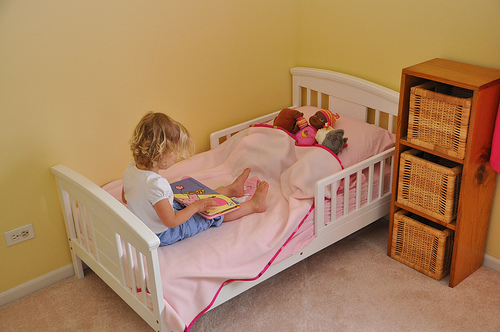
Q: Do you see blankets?
A: Yes, there is a blanket.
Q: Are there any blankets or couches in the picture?
A: Yes, there is a blanket.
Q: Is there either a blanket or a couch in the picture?
A: Yes, there is a blanket.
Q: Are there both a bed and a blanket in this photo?
A: Yes, there are both a blanket and a bed.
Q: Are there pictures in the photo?
A: No, there are no pictures.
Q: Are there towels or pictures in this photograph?
A: No, there are no pictures or towels.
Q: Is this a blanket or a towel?
A: This is a blanket.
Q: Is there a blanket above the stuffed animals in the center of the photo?
A: Yes, there is a blanket above the stuffed animals.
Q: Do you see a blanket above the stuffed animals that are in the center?
A: Yes, there is a blanket above the stuffed animals.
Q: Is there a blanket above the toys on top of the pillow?
A: Yes, there is a blanket above the stuffed animals.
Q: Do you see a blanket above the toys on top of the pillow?
A: Yes, there is a blanket above the stuffed animals.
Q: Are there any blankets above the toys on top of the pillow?
A: Yes, there is a blanket above the stuffed animals.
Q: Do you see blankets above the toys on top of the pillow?
A: Yes, there is a blanket above the stuffed animals.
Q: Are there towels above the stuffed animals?
A: No, there is a blanket above the stuffed animals.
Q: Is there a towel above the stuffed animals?
A: No, there is a blanket above the stuffed animals.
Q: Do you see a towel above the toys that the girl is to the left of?
A: No, there is a blanket above the stuffed animals.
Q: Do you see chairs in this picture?
A: No, there are no chairs.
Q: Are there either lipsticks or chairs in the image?
A: No, there are no chairs or lipsticks.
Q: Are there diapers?
A: No, there are no diapers.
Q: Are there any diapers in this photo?
A: No, there are no diapers.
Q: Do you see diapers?
A: No, there are no diapers.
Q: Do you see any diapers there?
A: No, there are no diapers.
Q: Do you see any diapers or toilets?
A: No, there are no diapers or toilets.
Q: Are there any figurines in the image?
A: No, there are no figurines.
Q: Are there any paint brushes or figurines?
A: No, there are no figurines or paint brushes.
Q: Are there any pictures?
A: No, there are no pictures.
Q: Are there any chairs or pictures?
A: No, there are no pictures or chairs.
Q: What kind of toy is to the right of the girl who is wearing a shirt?
A: The toys are stuffed animals.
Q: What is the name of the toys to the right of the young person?
A: The toys are stuffed animals.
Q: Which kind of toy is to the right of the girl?
A: The toys are stuffed animals.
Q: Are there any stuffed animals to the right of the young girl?
A: Yes, there are stuffed animals to the right of the girl.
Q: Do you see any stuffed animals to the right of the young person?
A: Yes, there are stuffed animals to the right of the girl.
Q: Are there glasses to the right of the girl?
A: No, there are stuffed animals to the right of the girl.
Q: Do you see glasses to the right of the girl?
A: No, there are stuffed animals to the right of the girl.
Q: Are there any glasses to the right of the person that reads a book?
A: No, there are stuffed animals to the right of the girl.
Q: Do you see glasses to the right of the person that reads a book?
A: No, there are stuffed animals to the right of the girl.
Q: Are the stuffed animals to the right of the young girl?
A: Yes, the stuffed animals are to the right of the girl.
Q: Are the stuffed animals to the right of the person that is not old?
A: Yes, the stuffed animals are to the right of the girl.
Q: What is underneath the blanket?
A: The stuffed animals are underneath the blanket.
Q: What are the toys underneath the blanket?
A: The toys are stuffed animals.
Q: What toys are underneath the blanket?
A: The toys are stuffed animals.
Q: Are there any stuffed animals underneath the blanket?
A: Yes, there are stuffed animals underneath the blanket.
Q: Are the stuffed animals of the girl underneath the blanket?
A: Yes, the stuffed animals are underneath the blanket.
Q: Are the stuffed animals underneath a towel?
A: No, the stuffed animals are underneath the blanket.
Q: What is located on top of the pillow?
A: The stuffed animals are on top of the pillow.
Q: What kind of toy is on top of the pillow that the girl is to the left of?
A: The toys are stuffed animals.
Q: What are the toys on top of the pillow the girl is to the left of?
A: The toys are stuffed animals.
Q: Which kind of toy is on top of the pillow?
A: The toys are stuffed animals.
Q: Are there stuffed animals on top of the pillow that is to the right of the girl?
A: Yes, there are stuffed animals on top of the pillow.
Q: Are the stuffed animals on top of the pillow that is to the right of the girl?
A: Yes, the stuffed animals are on top of the pillow.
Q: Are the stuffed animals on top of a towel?
A: No, the stuffed animals are on top of the pillow.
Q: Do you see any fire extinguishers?
A: No, there are no fire extinguishers.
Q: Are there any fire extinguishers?
A: No, there are no fire extinguishers.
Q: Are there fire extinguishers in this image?
A: No, there are no fire extinguishers.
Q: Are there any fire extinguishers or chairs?
A: No, there are no fire extinguishers or chairs.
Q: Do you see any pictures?
A: No, there are no pictures.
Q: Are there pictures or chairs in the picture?
A: No, there are no pictures or chairs.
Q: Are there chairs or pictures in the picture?
A: No, there are no pictures or chairs.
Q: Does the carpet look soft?
A: Yes, the carpet is soft.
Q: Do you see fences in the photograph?
A: No, there are no fences.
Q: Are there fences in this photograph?
A: No, there are no fences.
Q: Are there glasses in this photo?
A: No, there are no glasses.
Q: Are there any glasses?
A: No, there are no glasses.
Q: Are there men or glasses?
A: No, there are no glasses or men.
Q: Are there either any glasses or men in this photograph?
A: No, there are no glasses or men.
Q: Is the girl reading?
A: Yes, the girl is reading.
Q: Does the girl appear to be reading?
A: Yes, the girl is reading.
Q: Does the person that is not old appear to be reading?
A: Yes, the girl is reading.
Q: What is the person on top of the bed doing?
A: The girl is reading.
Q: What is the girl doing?
A: The girl is reading.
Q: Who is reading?
A: The girl is reading.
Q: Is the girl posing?
A: No, the girl is reading.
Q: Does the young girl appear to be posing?
A: No, the girl is reading.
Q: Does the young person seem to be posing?
A: No, the girl is reading.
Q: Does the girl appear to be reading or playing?
A: The girl is reading.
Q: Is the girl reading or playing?
A: The girl is reading.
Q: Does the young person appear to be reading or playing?
A: The girl is reading.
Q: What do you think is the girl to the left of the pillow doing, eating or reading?
A: The girl is reading.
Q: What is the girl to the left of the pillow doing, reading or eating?
A: The girl is reading.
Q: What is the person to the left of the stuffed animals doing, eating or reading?
A: The girl is reading.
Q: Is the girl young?
A: Yes, the girl is young.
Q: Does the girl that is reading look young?
A: Yes, the girl is young.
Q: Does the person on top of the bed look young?
A: Yes, the girl is young.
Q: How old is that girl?
A: The girl is young.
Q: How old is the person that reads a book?
A: The girl is young.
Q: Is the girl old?
A: No, the girl is young.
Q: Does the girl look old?
A: No, the girl is young.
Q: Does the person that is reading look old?
A: No, the girl is young.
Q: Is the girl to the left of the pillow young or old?
A: The girl is young.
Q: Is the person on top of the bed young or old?
A: The girl is young.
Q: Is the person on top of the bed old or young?
A: The girl is young.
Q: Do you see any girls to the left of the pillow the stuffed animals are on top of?
A: Yes, there is a girl to the left of the pillow.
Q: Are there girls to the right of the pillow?
A: No, the girl is to the left of the pillow.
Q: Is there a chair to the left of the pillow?
A: No, there is a girl to the left of the pillow.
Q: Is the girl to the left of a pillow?
A: Yes, the girl is to the left of a pillow.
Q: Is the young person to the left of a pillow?
A: Yes, the girl is to the left of a pillow.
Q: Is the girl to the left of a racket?
A: No, the girl is to the left of a pillow.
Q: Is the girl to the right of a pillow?
A: No, the girl is to the left of a pillow.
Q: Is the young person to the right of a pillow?
A: No, the girl is to the left of a pillow.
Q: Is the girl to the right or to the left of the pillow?
A: The girl is to the left of the pillow.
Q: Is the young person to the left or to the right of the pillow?
A: The girl is to the left of the pillow.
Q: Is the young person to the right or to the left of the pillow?
A: The girl is to the left of the pillow.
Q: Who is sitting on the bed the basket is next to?
A: The girl is sitting on the bed.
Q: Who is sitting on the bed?
A: The girl is sitting on the bed.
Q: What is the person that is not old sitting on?
A: The girl is sitting on the bed.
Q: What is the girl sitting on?
A: The girl is sitting on the bed.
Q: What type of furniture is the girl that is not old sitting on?
A: The girl is sitting on the bed.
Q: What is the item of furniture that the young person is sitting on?
A: The piece of furniture is a bed.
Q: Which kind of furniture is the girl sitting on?
A: The girl is sitting on the bed.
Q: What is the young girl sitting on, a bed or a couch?
A: The girl is sitting on a bed.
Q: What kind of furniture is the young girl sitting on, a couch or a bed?
A: The girl is sitting on a bed.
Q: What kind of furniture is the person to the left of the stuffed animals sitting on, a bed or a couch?
A: The girl is sitting on a bed.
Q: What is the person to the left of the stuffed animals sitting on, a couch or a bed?
A: The girl is sitting on a bed.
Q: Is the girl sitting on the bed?
A: Yes, the girl is sitting on the bed.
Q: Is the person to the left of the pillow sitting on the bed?
A: Yes, the girl is sitting on the bed.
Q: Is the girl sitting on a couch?
A: No, the girl is sitting on the bed.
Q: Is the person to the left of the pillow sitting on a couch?
A: No, the girl is sitting on the bed.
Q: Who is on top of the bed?
A: The girl is on top of the bed.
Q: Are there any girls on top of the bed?
A: Yes, there is a girl on top of the bed.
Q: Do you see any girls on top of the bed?
A: Yes, there is a girl on top of the bed.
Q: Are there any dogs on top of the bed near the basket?
A: No, there is a girl on top of the bed.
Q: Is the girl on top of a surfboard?
A: No, the girl is on top of the bed.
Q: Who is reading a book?
A: The girl is reading a book.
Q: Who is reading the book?
A: The girl is reading a book.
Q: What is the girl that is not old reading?
A: The girl is reading a book.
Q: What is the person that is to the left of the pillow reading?
A: The girl is reading a book.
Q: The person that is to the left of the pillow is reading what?
A: The girl is reading a book.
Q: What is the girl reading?
A: The girl is reading a book.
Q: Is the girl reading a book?
A: Yes, the girl is reading a book.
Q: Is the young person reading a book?
A: Yes, the girl is reading a book.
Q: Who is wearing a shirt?
A: The girl is wearing a shirt.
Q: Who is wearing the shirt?
A: The girl is wearing a shirt.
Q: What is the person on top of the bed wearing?
A: The girl is wearing a shirt.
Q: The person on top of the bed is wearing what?
A: The girl is wearing a shirt.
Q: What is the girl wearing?
A: The girl is wearing a shirt.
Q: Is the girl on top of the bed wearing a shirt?
A: Yes, the girl is wearing a shirt.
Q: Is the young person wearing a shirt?
A: Yes, the girl is wearing a shirt.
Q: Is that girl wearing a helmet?
A: No, the girl is wearing a shirt.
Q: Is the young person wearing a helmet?
A: No, the girl is wearing a shirt.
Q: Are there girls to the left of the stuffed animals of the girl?
A: Yes, there is a girl to the left of the stuffed animals.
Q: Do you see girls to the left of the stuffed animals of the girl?
A: Yes, there is a girl to the left of the stuffed animals.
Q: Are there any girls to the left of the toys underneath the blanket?
A: Yes, there is a girl to the left of the stuffed animals.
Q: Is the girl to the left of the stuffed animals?
A: Yes, the girl is to the left of the stuffed animals.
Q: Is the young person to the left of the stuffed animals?
A: Yes, the girl is to the left of the stuffed animals.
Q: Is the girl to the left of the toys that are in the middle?
A: Yes, the girl is to the left of the stuffed animals.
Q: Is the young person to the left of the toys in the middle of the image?
A: Yes, the girl is to the left of the stuffed animals.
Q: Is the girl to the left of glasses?
A: No, the girl is to the left of the stuffed animals.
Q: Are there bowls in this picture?
A: No, there are no bowls.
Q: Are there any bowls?
A: No, there are no bowls.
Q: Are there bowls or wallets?
A: No, there are no bowls or wallets.